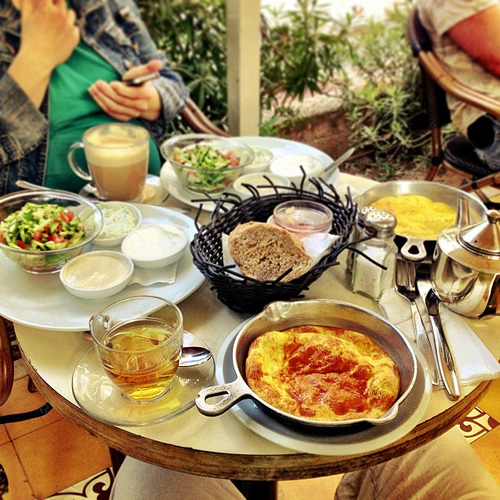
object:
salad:
[0, 199, 86, 248]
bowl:
[0, 187, 108, 279]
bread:
[225, 218, 314, 283]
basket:
[183, 158, 388, 321]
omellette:
[241, 319, 403, 426]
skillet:
[191, 294, 424, 441]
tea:
[103, 321, 182, 399]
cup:
[83, 291, 190, 403]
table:
[10, 161, 499, 494]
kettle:
[426, 191, 499, 323]